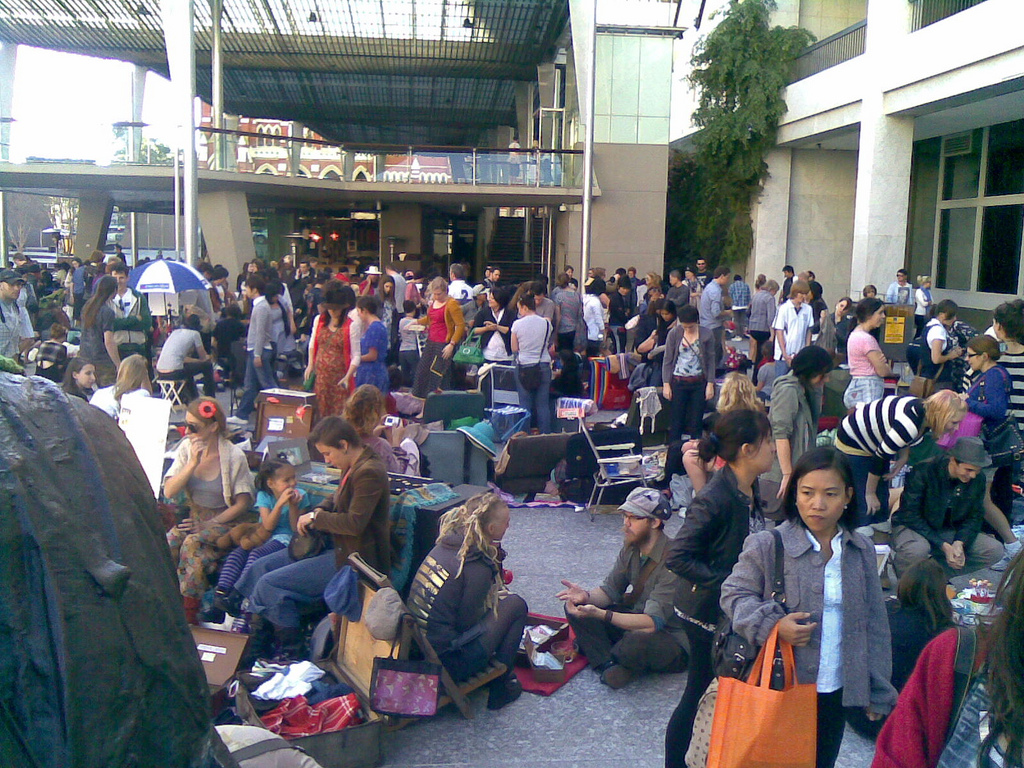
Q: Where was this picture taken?
A: At a outdoor market.